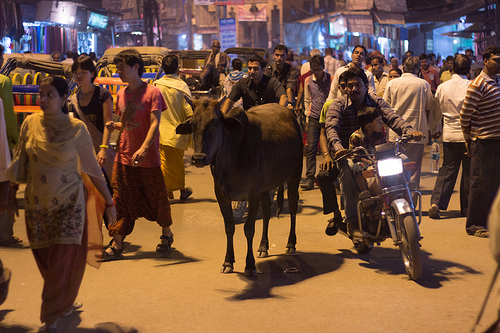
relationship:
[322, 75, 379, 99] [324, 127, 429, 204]
men on motorcycle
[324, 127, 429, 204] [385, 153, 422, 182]
motorcycle has headlight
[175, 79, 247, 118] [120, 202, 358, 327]
cow on street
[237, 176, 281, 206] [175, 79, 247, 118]
stomach of cow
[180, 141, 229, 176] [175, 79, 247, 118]
mouth of cow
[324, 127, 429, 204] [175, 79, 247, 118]
motorcycle beside cow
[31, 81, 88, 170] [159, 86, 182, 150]
woman wearing yellow